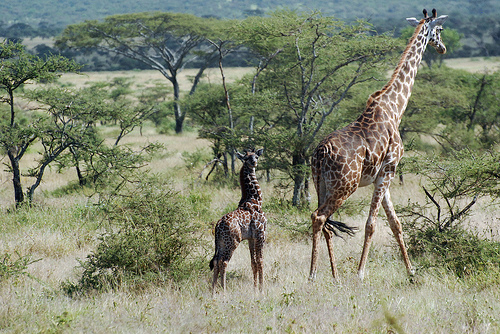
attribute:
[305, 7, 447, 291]
giraffe — tall, cream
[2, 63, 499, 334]
ground — grassy, brown, dry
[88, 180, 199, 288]
bush — dry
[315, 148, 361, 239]
tail — wavy, black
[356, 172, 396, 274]
leg — long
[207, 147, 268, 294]
baby — giraffe, curious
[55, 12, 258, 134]
tree — tall, flat, grey